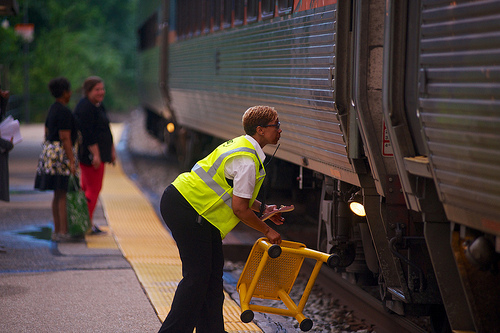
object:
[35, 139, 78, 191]
skirt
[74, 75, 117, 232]
passenger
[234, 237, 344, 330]
stool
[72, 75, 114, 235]
lady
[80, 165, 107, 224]
red pant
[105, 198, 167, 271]
yellow pavement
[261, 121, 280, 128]
eyeglasses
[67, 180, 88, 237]
green bag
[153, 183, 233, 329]
black pants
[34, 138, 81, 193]
dress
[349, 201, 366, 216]
light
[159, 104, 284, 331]
person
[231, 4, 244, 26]
window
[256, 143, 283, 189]
walkie talkie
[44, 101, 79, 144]
shirt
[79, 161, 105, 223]
pants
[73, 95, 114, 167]
sweater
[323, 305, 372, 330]
gravel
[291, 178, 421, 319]
train tracks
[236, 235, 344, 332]
stepstool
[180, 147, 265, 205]
vest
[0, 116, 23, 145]
paper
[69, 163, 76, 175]
right hand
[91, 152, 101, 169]
right hand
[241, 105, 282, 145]
head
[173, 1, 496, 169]
train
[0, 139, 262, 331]
platform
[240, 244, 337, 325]
yellow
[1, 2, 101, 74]
trees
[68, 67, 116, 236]
woman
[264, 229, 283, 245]
hand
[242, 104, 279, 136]
hair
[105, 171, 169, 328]
line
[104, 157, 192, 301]
stripe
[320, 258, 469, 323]
tracks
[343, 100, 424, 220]
stairs